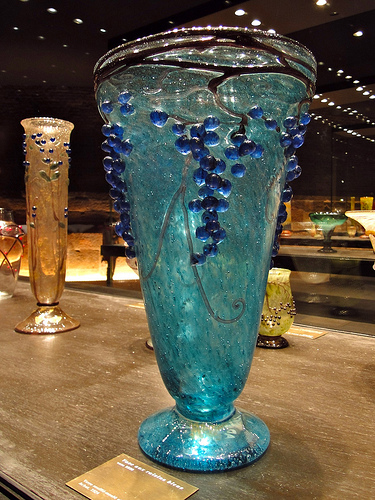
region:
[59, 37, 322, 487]
a large blue piece of art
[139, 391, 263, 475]
the bottom part of a vase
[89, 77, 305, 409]
the main part of a vase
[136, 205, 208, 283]
a piece of metal in a vase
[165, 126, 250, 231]
a bunch of circular designs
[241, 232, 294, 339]
a small yellow vase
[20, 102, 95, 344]
a tall tan colored vase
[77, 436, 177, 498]
a small gold plate with a description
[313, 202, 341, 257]
a piece of green art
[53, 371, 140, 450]
a large wooden table top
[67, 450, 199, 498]
place card on the table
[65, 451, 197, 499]
gold place card on the table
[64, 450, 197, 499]
place card in front of blue glass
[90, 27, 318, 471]
large blue glass with beads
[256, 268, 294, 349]
small, yellow glass with brown beads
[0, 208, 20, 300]
clear glass on the left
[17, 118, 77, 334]
tall gold glass with blue beads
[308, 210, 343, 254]
large green glass in the back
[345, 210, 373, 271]
large white martini glass on the right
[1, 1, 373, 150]
rows of ceiling lights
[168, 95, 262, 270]
Blue stones on the vase.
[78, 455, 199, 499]
A card telling about the vase.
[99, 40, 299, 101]
Swirled design in the vase.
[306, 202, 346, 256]
A green vase on display.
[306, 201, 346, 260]
Green vase sitting on a shelf.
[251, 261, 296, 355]
Small yellow vase on the counter.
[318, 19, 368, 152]
Many lights dot the ceiling.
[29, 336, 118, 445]
A wood counter to display the vases.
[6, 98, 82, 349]
Very tall amber colored vase.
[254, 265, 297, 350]
object on the table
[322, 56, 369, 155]
lights strung on the ceiling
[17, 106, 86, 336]
tall structure with blue knobs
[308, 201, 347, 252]
green structure on table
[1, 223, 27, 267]
red beads on the structure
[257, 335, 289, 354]
brown base to structure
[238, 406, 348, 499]
shadow of the vase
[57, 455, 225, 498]
place card labeling the vase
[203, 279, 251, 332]
swirl decorating the vase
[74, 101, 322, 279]
grapes on the vase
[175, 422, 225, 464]
reflection of light on the vase bottom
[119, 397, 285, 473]
base of the vase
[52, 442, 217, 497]
white writing on the place card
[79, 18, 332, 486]
vase on display table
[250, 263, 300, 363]
vase behind the vase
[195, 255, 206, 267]
blue dot on cup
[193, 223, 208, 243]
blue dot on cup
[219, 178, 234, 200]
blue dot on cup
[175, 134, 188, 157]
blue dot on cup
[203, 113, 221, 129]
blue dot on cup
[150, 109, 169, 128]
blue dot on cup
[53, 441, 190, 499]
brown card with white writing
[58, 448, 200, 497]
brown card with white writing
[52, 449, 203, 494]
brown card with white writing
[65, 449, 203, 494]
brown card with white writing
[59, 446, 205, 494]
brown card with white writing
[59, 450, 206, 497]
brown card with white writing